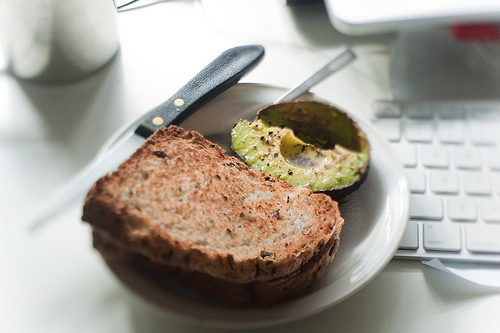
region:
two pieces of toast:
[67, 22, 436, 332]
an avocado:
[103, 38, 498, 290]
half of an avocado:
[15, 48, 433, 309]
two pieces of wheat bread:
[61, 80, 458, 317]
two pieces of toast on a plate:
[60, 106, 397, 288]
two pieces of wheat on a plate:
[50, 81, 407, 330]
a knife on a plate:
[37, 25, 377, 267]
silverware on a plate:
[51, 43, 446, 330]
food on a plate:
[87, 95, 489, 319]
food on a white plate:
[85, 87, 492, 310]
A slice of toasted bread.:
[73, 126, 343, 304]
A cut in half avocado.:
[226, 101, 372, 194]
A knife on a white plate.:
[22, 23, 268, 245]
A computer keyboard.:
[323, 90, 499, 270]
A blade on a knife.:
[21, 120, 154, 240]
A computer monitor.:
[316, 2, 499, 86]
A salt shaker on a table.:
[0, 0, 132, 78]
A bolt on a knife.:
[173, 95, 194, 115]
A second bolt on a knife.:
[147, 107, 171, 132]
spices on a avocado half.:
[257, 122, 287, 183]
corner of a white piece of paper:
[428, 262, 497, 294]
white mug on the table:
[0, 16, 129, 73]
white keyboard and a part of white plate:
[373, 95, 498, 231]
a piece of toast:
[125, 167, 310, 272]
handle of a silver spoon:
[274, 51, 364, 98]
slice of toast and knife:
[19, 28, 281, 220]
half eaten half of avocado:
[233, 96, 370, 201]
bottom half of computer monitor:
[328, 0, 493, 52]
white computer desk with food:
[21, 250, 85, 322]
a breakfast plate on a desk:
[62, 28, 451, 310]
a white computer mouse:
[5, 2, 140, 92]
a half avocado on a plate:
[233, 98, 375, 189]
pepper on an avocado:
[253, 120, 285, 167]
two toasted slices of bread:
[103, 152, 325, 293]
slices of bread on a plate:
[86, 177, 362, 331]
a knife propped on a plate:
[17, 27, 264, 234]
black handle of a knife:
[128, 37, 257, 127]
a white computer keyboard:
[388, 90, 497, 275]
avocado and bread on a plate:
[91, 57, 401, 319]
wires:
[118, 0, 213, 18]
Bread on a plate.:
[109, 155, 327, 280]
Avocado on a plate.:
[243, 105, 380, 198]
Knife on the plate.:
[21, 114, 181, 222]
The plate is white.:
[353, 187, 415, 284]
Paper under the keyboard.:
[424, 251, 499, 293]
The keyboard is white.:
[371, 93, 497, 261]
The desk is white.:
[18, 243, 87, 320]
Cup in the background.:
[6, 2, 133, 78]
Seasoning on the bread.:
[147, 155, 252, 250]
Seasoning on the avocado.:
[245, 120, 359, 201]